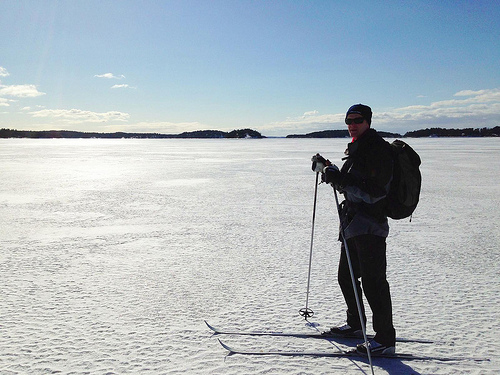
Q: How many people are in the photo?
A: One.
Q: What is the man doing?
A: Cross country skiing.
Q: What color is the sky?
A: Blue.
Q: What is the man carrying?
A: A backpack.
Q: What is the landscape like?
A: Flat and snow-covered.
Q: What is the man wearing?
A: Snow gear and sunglasses.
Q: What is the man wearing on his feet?
A: Skis and boots.